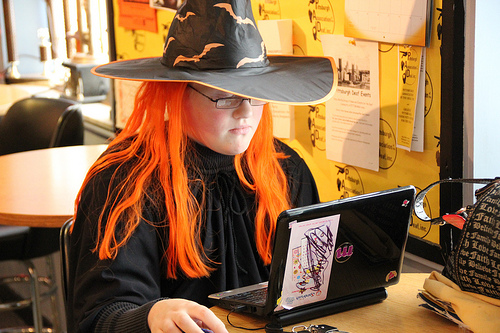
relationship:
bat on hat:
[157, 27, 177, 57] [77, 0, 354, 116]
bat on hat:
[169, 5, 201, 27] [77, 0, 354, 116]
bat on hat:
[166, 35, 231, 74] [77, 0, 354, 116]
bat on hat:
[215, 0, 261, 36] [77, 0, 354, 116]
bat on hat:
[231, 34, 275, 75] [77, 0, 354, 116]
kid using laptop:
[70, 0, 343, 333] [180, 178, 434, 327]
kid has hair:
[70, 0, 343, 333] [58, 57, 313, 282]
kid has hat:
[70, 0, 343, 333] [77, 0, 354, 116]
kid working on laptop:
[70, 0, 343, 333] [180, 178, 434, 327]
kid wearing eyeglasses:
[70, 0, 343, 333] [180, 82, 290, 118]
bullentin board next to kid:
[113, 0, 435, 244] [70, 0, 343, 333]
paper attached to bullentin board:
[332, 0, 447, 54] [113, 0, 435, 244]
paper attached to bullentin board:
[312, 29, 390, 177] [113, 0, 435, 244]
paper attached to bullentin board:
[249, 11, 300, 144] [113, 0, 435, 244]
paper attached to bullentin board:
[382, 32, 441, 162] [113, 0, 435, 244]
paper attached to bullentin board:
[110, 0, 168, 42] [113, 0, 435, 244]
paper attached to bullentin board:
[149, 0, 198, 14] [113, 0, 435, 244]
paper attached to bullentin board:
[108, 62, 174, 136] [113, 0, 435, 244]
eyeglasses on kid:
[180, 82, 290, 118] [70, 0, 343, 333]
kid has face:
[70, 0, 343, 333] [196, 85, 274, 155]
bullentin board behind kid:
[113, 0, 435, 244] [70, 0, 343, 333]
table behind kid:
[0, 133, 128, 226] [70, 0, 343, 333]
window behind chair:
[27, 0, 130, 125] [0, 85, 91, 153]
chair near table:
[0, 85, 91, 153] [0, 133, 128, 226]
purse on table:
[410, 159, 500, 309] [169, 265, 499, 332]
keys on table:
[290, 319, 343, 330] [371, 297, 417, 324]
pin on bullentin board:
[348, 30, 360, 48] [121, 0, 450, 224]